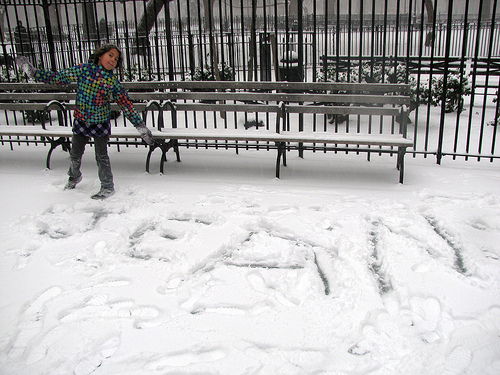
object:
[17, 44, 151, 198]
girl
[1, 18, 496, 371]
snow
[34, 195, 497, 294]
name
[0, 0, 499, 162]
fence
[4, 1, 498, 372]
park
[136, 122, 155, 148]
hand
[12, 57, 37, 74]
hand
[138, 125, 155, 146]
glove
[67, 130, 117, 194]
jeans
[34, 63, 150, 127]
jacket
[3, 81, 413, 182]
bench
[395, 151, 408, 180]
leg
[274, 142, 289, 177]
leg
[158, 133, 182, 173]
leg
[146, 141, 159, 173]
leg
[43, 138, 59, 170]
leg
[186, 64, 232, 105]
bush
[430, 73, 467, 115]
bush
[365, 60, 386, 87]
bush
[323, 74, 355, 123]
bush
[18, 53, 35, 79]
glove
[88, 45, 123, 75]
hair